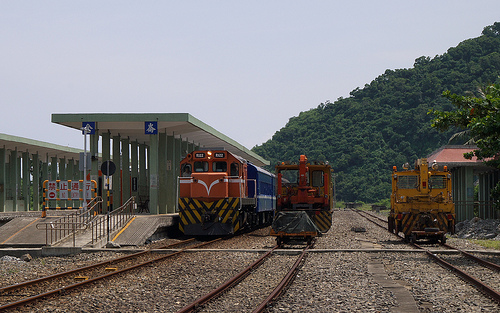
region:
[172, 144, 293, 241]
passenger train on left track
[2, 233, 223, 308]
train track on left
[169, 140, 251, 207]
orange front of train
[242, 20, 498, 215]
dark green leafy hillside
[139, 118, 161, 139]
blue sign on train platform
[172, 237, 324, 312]
train track in middle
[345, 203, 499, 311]
train track on right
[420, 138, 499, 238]
building with red roof on right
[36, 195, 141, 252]
handrails on sloped ramp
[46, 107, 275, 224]
passenger platform near train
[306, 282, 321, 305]
pebbles near the track.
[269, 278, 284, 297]
track made of steel.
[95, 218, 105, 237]
railing near the platform.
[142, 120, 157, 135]
sign on the platform.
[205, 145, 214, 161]
light on the train.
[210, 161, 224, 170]
window on the train.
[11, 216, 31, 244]
yellow paint on the platform.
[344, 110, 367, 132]
trees on the hillside.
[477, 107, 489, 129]
leaves on the tree.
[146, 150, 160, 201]
beam on the platform.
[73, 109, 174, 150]
the signs are blue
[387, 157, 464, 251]
the vehicle is orange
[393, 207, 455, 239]
orange and black stripes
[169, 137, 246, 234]
front of train is red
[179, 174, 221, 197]
white lines on train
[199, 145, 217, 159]
light on the train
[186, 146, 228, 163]
white numbers on the train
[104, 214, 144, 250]
yellow line on the pavement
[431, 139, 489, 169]
the roof is red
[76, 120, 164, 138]
white pictures on the signs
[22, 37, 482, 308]
this is at a transit stop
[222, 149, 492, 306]
these push trains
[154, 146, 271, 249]
this is a train engine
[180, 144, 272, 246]
the train engine is orange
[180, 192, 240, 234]
the trains bumper is striped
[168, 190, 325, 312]
the bumper is striped yellow and black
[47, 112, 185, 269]
this is a train platform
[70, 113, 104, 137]
this sign is blue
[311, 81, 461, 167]
the hillside is covered in trees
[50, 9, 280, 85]
the sky is overcast and gray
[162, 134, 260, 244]
red train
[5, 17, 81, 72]
white clouds in blue sky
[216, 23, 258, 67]
white clouds in blue sky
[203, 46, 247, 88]
white clouds in blue sky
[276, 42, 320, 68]
white clouds in blue sky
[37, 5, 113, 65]
white clouds in blue sky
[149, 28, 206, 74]
white clouds in blue sky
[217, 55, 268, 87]
white clouds in blue sky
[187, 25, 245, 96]
white clouds in blue sky